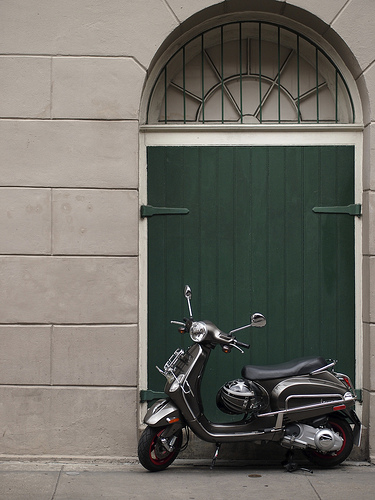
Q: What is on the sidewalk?
A: Bike.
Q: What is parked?
A: Bike.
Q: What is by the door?
A: A bike.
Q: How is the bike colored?
A: Black.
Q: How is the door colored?
A: Green.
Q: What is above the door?
A: Archway.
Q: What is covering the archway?
A: Metal.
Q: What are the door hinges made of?
A: Metal.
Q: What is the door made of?
A: Wood.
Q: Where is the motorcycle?
A: In front of the door.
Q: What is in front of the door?
A: Motorcycle.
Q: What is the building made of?
A: Cement.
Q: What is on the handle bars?
A: Side mirrors.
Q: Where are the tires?
A: On the motorcycle.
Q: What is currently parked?
A: A bike.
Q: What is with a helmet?
A: A bike.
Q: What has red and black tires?
A: A bike.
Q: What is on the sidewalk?
A: A motorcycle.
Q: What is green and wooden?
A: A door.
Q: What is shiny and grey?
A: A scooter.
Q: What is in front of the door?
A: A motorcycle.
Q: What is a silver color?
A: A helmet.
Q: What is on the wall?
A: Bricks.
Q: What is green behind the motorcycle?
A: A door.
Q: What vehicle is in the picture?
A: A scooter bike.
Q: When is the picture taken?
A: Daytime.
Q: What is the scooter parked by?
A: Door.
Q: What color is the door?
A: Green.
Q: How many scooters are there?
A: One.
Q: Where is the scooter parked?
A: On the pavement.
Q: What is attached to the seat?
A: A helmet.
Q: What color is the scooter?
A: Black.